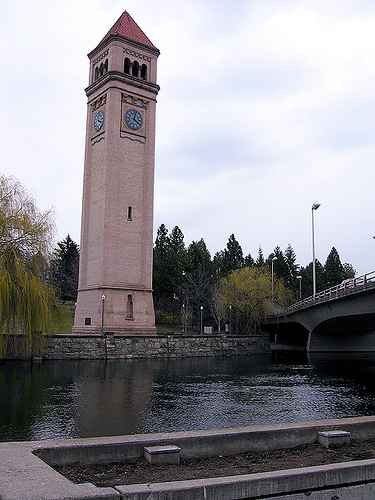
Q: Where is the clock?
A: On the tower.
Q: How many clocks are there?
A: 2.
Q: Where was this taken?
A: By a river.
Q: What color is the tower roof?
A: Red.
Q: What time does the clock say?
A: 12:20.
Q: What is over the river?
A: Bridge.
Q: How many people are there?
A: 0.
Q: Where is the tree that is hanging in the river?
A: To the left opposite bank.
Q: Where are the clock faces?
A: On the tower.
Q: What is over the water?
A: A bridge.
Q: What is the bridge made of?
A: Concrete.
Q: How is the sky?
A: Cloudy.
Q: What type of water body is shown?
A: River.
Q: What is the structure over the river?
A: Bridge.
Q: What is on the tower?
A: Clocks.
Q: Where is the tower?
A: Next to the water.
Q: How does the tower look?
A: Tall and light tan.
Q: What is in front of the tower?
A: A river.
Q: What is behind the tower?
A: Trees.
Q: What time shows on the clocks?
A: 1220.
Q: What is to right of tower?
A: Bridge.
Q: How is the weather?
A: Overcast.